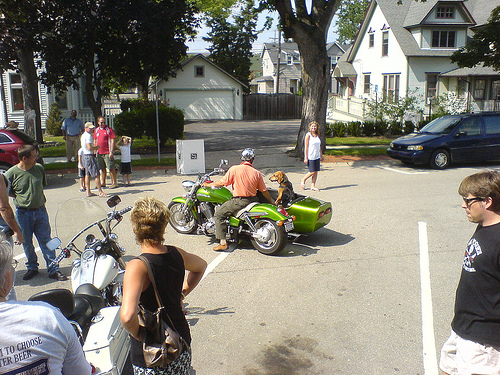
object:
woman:
[299, 120, 324, 191]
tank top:
[305, 132, 322, 161]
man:
[439, 168, 499, 374]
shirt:
[449, 220, 499, 348]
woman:
[120, 195, 206, 375]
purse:
[119, 196, 207, 374]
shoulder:
[132, 255, 190, 370]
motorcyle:
[166, 159, 332, 255]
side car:
[164, 158, 333, 255]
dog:
[269, 171, 297, 208]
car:
[0, 128, 46, 185]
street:
[1, 105, 500, 374]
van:
[386, 109, 499, 169]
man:
[93, 116, 119, 188]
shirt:
[92, 125, 116, 155]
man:
[4, 144, 67, 281]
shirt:
[4, 162, 48, 209]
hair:
[130, 197, 172, 246]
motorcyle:
[28, 195, 147, 375]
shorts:
[307, 157, 320, 172]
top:
[127, 244, 190, 368]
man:
[201, 147, 277, 251]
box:
[176, 138, 206, 175]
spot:
[239, 331, 342, 374]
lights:
[319, 207, 331, 217]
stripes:
[189, 221, 441, 375]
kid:
[115, 136, 133, 187]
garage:
[150, 52, 248, 120]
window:
[194, 64, 206, 78]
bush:
[113, 110, 147, 140]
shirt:
[219, 161, 267, 197]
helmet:
[240, 147, 255, 161]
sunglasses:
[463, 197, 484, 209]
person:
[1, 234, 98, 374]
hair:
[0, 237, 19, 295]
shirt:
[0, 299, 94, 373]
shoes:
[213, 243, 229, 251]